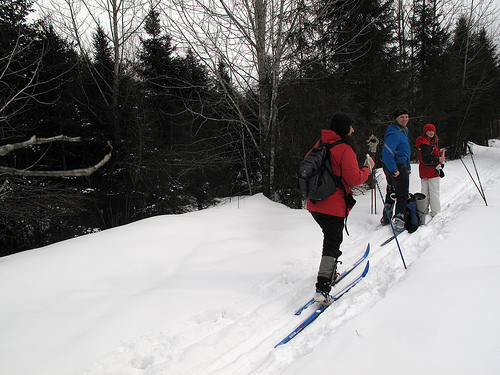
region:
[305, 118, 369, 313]
THAT IS A PERSON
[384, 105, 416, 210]
THAT IS A PERSON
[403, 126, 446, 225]
THAT IS A PERSON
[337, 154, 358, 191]
THIS IS A RED JACKET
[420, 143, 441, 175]
THIS IS A RED JACKET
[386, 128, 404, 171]
THIS IS A BLUE JACKET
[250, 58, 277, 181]
THAT IS A TREE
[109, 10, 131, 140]
THAT IS A TREE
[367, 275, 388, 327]
A PATCH OF SNOW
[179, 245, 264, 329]
A PATCH OF SNOW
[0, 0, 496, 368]
People are outside in the snow.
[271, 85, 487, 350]
Three people are on skis.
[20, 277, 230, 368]
The snow is white.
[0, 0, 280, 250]
Evegreen trees are in the distance.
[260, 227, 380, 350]
The woman has skis on her feet.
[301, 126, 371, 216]
The woman is wearing a red jacket.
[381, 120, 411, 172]
The man is wearing a blue jacket.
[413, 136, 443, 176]
Another woman wearing a red jacket.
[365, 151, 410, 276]
The woman is holding a ski pole.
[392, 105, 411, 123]
The man is wearing a hat.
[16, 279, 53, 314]
white snow on ground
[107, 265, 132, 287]
white snow on ground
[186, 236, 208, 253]
white snow on ground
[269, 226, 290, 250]
white snow on ground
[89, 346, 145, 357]
white snow on ground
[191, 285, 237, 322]
white snow on ground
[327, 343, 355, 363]
white snow on ground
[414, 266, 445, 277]
white snow on ground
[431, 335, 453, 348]
white snow on ground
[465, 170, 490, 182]
white snow on ground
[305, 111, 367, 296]
this is a person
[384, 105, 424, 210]
this is a person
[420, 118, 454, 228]
this is a person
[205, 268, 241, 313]
this is patch of snow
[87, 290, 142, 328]
this is patch of snow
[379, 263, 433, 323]
this is patch of snow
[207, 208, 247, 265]
this is patch of snow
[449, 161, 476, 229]
this is patch of snow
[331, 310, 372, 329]
this is patch of snow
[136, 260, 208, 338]
this is patch of snow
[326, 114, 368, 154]
Person wearing black hat.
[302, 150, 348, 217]
Gray back pack on person's back.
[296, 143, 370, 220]
Person wearing red coat.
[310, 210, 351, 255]
Person wearing black pants.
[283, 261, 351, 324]
2 blue skis on person's feet.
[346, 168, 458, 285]
Person has ski pole in hand.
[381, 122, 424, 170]
Person wearing blue coat.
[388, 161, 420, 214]
Person wearing black pants.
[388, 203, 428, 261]
Person wearing gray boots.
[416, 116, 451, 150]
Person wearing red hat.